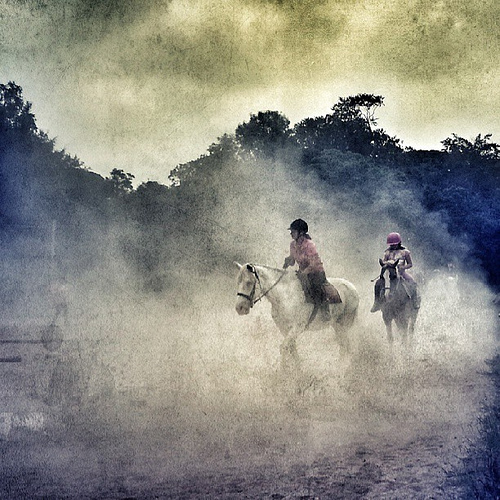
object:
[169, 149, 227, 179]
tree top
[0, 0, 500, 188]
sky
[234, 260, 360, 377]
horse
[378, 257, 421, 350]
horse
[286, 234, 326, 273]
shirt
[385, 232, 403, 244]
helmet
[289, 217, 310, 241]
head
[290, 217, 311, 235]
helmet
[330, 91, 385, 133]
tree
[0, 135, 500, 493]
fog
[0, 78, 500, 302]
forest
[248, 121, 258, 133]
leaves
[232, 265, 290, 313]
bridle